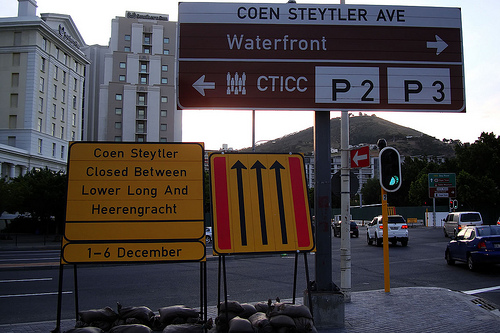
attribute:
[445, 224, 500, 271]
car — blue, driving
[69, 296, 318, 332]
sandbags — brown, piled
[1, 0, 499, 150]
sky — cloudy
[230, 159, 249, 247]
arrow — black, pointing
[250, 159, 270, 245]
arrow — black, pointing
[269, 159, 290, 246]
arrow — black, pointing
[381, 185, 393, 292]
pole — yellow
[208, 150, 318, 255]
sign — yellow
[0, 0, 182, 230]
building — tall, white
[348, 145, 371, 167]
sign — red, white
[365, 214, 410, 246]
car — white, moving, driving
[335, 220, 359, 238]
car — driving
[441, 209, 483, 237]
car — driving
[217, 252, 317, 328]
post — metal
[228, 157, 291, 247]
arrows — facing upwards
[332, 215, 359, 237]
car — intersection.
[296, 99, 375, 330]
pole — yellow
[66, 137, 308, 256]
sign — bottom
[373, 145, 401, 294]
light signal — Green traffic light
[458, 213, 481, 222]
rear window — rear 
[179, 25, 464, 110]
sign — red, white 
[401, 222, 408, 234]
light — rear tail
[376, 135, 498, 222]
trees — background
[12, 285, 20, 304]
lines — White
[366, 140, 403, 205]
signal — traffic 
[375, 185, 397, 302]
yellow post — Yellow 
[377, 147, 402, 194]
traffic light — green, traffic 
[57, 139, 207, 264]
sign — yellow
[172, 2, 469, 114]
sign — directional, brown, white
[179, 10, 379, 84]
sign — waterfront.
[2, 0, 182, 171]
tall building — tall tan.